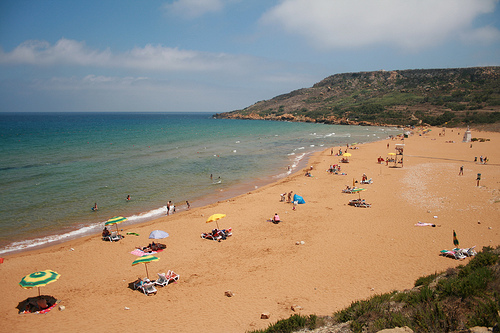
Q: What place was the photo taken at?
A: It was taken at the beach.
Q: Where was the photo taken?
A: It was taken at the beach.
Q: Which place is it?
A: It is a beach.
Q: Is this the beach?
A: Yes, it is the beach.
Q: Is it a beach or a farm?
A: It is a beach.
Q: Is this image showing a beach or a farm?
A: It is showing a beach.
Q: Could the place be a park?
A: No, it is a beach.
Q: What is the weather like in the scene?
A: It is clear.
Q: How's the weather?
A: It is clear.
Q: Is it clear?
A: Yes, it is clear.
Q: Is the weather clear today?
A: Yes, it is clear.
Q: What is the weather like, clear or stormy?
A: It is clear.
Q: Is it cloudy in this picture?
A: No, it is clear.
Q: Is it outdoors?
A: Yes, it is outdoors.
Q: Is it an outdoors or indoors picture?
A: It is outdoors.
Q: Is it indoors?
A: No, it is outdoors.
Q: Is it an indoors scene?
A: No, it is outdoors.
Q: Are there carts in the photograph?
A: No, there are no carts.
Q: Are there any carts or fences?
A: No, there are no carts or fences.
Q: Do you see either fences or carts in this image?
A: No, there are no carts or fences.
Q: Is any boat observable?
A: No, there are no boats.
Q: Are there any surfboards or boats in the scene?
A: No, there are no boats or surfboards.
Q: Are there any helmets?
A: No, there are no helmets.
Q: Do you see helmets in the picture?
A: No, there are no helmets.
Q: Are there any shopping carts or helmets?
A: No, there are no helmets or shopping carts.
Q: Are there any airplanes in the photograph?
A: No, there are no airplanes.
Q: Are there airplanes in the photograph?
A: No, there are no airplanes.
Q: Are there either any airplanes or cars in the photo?
A: No, there are no airplanes or cars.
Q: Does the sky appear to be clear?
A: Yes, the sky is clear.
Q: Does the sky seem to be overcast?
A: No, the sky is clear.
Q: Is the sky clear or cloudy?
A: The sky is clear.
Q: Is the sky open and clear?
A: Yes, the sky is open and clear.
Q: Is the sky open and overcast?
A: No, the sky is open but clear.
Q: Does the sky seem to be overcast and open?
A: No, the sky is open but clear.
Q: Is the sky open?
A: Yes, the sky is open.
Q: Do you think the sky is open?
A: Yes, the sky is open.